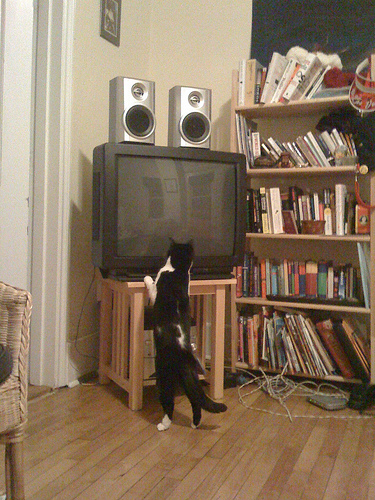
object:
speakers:
[168, 85, 211, 150]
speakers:
[108, 76, 156, 144]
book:
[243, 252, 251, 292]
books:
[353, 262, 361, 300]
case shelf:
[229, 61, 374, 392]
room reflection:
[119, 156, 234, 258]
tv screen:
[116, 153, 238, 253]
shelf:
[240, 165, 355, 178]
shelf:
[243, 230, 370, 241]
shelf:
[234, 360, 362, 383]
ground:
[262, 440, 338, 471]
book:
[304, 260, 317, 299]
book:
[317, 259, 330, 301]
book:
[259, 259, 265, 298]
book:
[271, 263, 278, 298]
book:
[339, 263, 344, 299]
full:
[228, 298, 371, 387]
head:
[167, 234, 195, 266]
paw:
[155, 421, 165, 430]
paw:
[190, 421, 200, 426]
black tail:
[192, 376, 228, 413]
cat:
[142, 234, 227, 431]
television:
[90, 142, 246, 281]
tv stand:
[96, 276, 238, 411]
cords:
[233, 363, 363, 421]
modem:
[307, 385, 343, 412]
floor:
[2, 352, 374, 498]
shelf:
[234, 295, 369, 315]